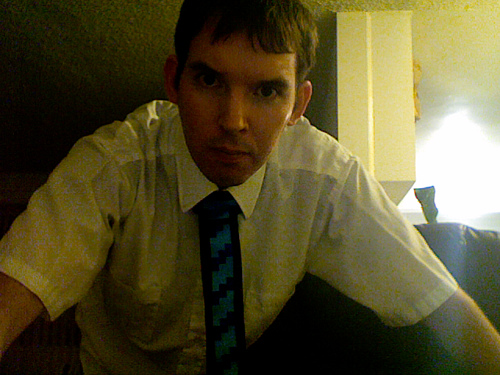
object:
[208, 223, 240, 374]
pattern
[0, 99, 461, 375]
shirt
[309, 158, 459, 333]
sleeve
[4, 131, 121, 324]
sleeve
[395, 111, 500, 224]
light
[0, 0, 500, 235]
wall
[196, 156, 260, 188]
facial stubble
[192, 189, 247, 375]
tie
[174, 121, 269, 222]
collar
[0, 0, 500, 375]
man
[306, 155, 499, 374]
arms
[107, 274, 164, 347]
shirt pocket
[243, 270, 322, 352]
shirt pocket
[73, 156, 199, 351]
shirt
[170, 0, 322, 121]
hair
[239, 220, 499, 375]
couch